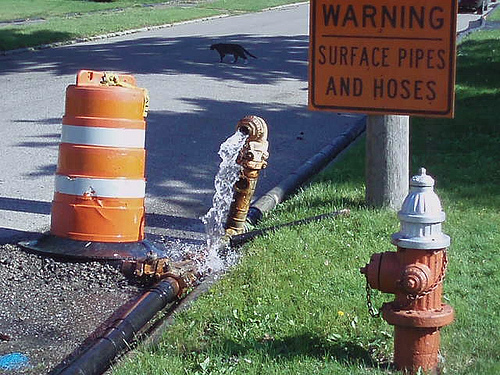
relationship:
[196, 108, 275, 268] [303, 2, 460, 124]
water leak next sign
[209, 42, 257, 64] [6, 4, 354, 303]
black cat on road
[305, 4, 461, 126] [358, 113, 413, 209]
orange sign on post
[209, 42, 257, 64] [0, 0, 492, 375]
black cat crossing road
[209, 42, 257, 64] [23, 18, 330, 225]
black cat crossing street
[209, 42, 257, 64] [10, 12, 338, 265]
black cat crossing street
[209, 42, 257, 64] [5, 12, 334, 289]
black cat crossing street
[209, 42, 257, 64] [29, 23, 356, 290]
black cat crossing street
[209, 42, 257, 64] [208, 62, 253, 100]
black cat crossing street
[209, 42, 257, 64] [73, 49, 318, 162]
black cat crosses road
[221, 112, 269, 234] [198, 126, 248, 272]
pipe contains water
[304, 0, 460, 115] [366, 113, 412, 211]
orange sign on post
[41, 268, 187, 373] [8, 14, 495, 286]
surface pipe along road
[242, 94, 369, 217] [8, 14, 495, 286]
surface pipe along road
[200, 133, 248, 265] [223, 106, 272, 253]
water inside pipes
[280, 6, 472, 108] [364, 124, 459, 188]
sign set on post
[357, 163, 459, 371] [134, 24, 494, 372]
hydrant in grass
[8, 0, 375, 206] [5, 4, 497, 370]
road in area